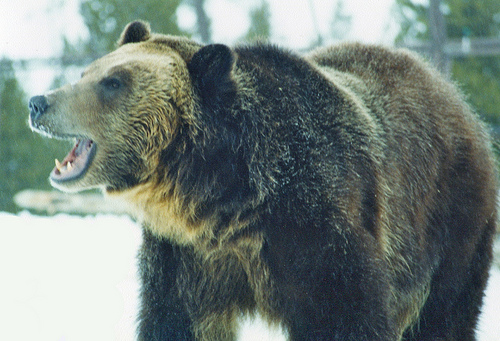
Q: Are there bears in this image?
A: Yes, there is a bear.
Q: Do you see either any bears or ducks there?
A: Yes, there is a bear.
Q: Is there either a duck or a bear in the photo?
A: Yes, there is a bear.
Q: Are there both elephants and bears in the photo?
A: No, there is a bear but no elephants.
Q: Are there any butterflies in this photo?
A: No, there are no butterflies.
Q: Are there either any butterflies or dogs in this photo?
A: No, there are no butterflies or dogs.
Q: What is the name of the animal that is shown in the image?
A: The animal is a bear.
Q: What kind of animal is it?
A: The animal is a bear.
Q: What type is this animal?
A: This is a bear.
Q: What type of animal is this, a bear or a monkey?
A: This is a bear.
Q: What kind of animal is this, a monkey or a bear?
A: This is a bear.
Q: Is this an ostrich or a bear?
A: This is a bear.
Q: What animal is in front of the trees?
A: The bear is in front of the trees.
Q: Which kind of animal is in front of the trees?
A: The animal is a bear.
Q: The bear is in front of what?
A: The bear is in front of the trees.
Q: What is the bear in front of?
A: The bear is in front of the trees.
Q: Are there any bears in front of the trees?
A: Yes, there is a bear in front of the trees.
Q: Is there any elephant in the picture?
A: No, there are no elephants.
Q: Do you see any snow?
A: Yes, there is snow.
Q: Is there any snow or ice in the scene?
A: Yes, there is snow.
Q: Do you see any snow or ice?
A: Yes, there is snow.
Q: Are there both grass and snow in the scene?
A: No, there is snow but no grass.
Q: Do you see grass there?
A: No, there is no grass.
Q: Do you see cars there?
A: No, there are no cars.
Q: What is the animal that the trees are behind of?
A: The animal is a bear.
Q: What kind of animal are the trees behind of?
A: The trees are behind the bear.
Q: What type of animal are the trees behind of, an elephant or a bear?
A: The trees are behind a bear.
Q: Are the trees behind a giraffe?
A: No, the trees are behind the bear.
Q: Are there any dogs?
A: No, there are no dogs.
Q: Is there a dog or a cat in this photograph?
A: No, there are no dogs or cats.